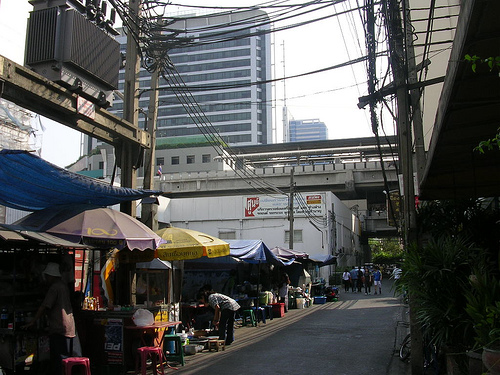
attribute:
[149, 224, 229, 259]
umbrella — large, yellow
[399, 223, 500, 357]
leaves — green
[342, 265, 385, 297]
people — walking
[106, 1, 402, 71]
lines — black, suspended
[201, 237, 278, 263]
tarp — large, blue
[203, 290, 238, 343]
person — bending over, looking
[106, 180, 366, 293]
building — white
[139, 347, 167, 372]
stool — red, small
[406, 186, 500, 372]
plants — potted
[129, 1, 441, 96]
wires — above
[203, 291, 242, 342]
woman — bent over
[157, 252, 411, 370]
street — grey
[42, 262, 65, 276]
hat — white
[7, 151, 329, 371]
shops — little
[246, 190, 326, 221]
sign — red, white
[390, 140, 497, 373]
bush — green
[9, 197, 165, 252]
umbrella — purple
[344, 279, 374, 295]
pants — long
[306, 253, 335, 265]
tarp — blur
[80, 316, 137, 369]
signs — different